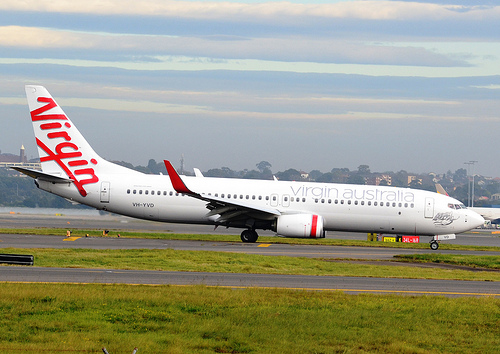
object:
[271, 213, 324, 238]
engine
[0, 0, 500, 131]
clouds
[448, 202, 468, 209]
windows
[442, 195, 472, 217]
cockpit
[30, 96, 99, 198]
logo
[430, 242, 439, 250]
wheel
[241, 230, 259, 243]
wheel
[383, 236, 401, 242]
sign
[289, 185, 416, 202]
brand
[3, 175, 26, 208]
trees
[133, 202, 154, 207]
code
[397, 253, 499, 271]
grass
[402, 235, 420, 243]
orange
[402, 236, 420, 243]
sign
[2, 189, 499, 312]
airport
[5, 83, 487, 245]
airplane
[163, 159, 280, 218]
airplane wing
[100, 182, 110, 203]
doors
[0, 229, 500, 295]
runway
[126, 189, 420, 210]
windows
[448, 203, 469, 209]
windshields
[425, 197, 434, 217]
door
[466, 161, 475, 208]
poles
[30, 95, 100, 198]
lettering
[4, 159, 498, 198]
background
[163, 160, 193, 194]
winglet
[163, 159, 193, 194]
upturned tip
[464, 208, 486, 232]
nose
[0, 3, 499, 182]
sky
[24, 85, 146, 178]
tail wing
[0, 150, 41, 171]
building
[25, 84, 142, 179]
tail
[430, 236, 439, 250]
landing gear